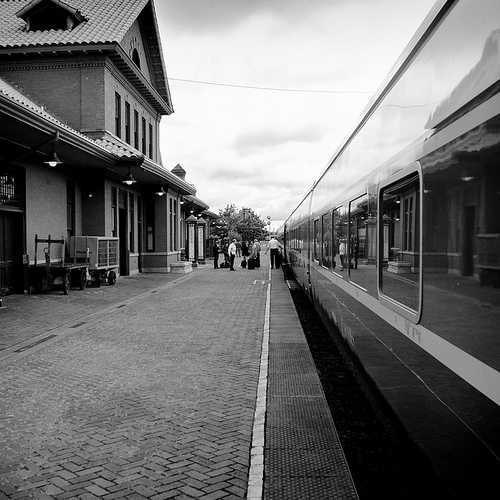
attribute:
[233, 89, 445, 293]
train — reflective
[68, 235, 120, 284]
cart — white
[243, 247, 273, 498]
line — white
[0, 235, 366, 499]
sidewalk — Brick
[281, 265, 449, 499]
gap — large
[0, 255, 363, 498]
road — paved